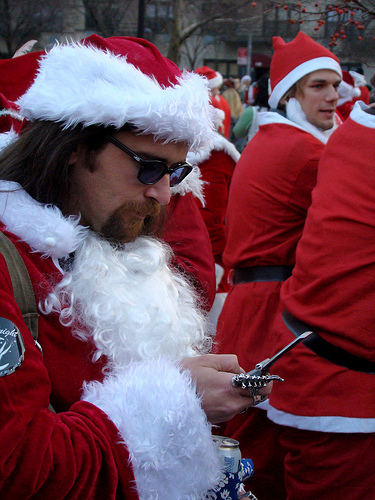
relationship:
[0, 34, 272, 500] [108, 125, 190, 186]
guy wearing sunglasses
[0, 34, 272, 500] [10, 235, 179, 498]
guy has body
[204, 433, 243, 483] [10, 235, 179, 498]
can on body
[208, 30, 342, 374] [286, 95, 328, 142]
guy has beard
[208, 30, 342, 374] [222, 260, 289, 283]
guy wearing black belt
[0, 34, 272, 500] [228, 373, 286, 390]
guy wearing ring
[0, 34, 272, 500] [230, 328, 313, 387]
guy has phone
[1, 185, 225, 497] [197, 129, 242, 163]
jacket has cuff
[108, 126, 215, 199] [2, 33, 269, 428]
sunglasses of santa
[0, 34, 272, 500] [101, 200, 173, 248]
guy has goatee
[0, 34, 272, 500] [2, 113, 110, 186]
guy has hair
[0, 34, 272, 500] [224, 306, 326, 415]
guy holding cell phone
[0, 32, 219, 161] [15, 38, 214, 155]
hat has fur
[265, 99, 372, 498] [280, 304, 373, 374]
person wearing belt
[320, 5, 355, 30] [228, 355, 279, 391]
limbs with bulbs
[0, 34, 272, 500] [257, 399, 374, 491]
guy wearing pants